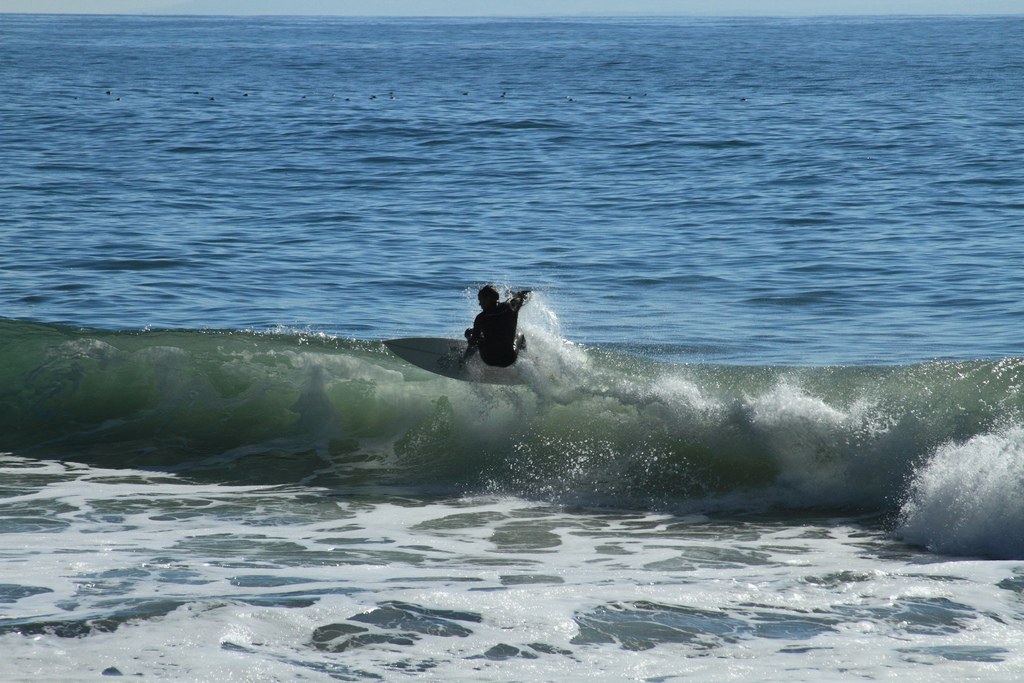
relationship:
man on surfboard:
[462, 284, 531, 368] [367, 332, 545, 387]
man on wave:
[462, 284, 531, 368] [6, 295, 1018, 548]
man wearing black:
[462, 284, 531, 368] [474, 309, 514, 359]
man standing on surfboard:
[457, 286, 525, 358] [379, 329, 554, 384]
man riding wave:
[470, 270, 531, 357] [29, 318, 1017, 554]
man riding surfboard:
[462, 284, 531, 368] [387, 337, 563, 387]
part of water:
[12, 465, 1021, 669] [9, 13, 1018, 672]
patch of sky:
[644, 0, 873, 16] [1, 0, 1021, 18]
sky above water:
[1, 0, 1021, 18] [18, 28, 1001, 258]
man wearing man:
[462, 284, 531, 368] [462, 284, 531, 368]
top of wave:
[660, 381, 998, 446] [29, 318, 1017, 554]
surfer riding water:
[425, 236, 575, 386] [632, 297, 861, 501]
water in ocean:
[632, 297, 861, 501] [437, 351, 617, 485]